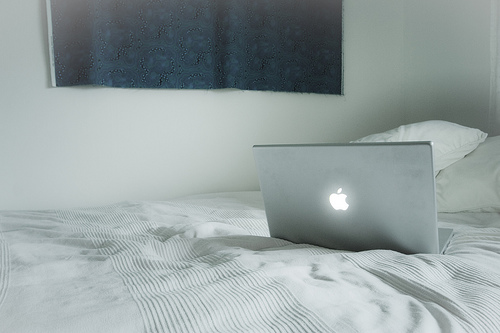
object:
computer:
[250, 141, 454, 255]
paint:
[8, 96, 102, 141]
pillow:
[436, 135, 499, 215]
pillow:
[349, 118, 489, 177]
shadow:
[347, 253, 470, 321]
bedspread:
[1, 187, 500, 332]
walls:
[3, 2, 500, 214]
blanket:
[3, 190, 500, 332]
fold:
[369, 270, 471, 333]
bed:
[0, 192, 499, 333]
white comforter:
[7, 207, 500, 332]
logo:
[328, 187, 349, 211]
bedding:
[2, 201, 497, 331]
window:
[44, 0, 345, 95]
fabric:
[46, 2, 343, 94]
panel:
[46, 0, 348, 97]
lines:
[80, 211, 337, 333]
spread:
[1, 185, 500, 333]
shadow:
[321, 169, 411, 249]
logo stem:
[337, 188, 343, 194]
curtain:
[49, 3, 347, 97]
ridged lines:
[63, 202, 328, 332]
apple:
[329, 188, 349, 211]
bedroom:
[0, 0, 499, 332]